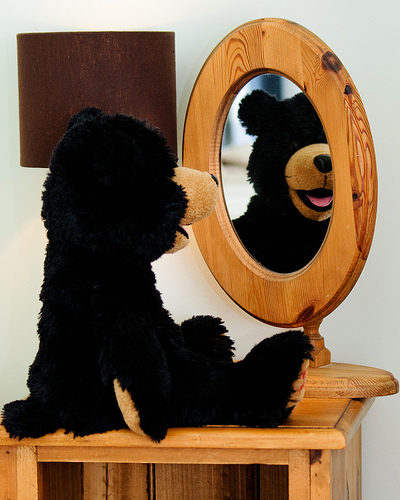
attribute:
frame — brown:
[175, 22, 390, 324]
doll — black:
[0, 97, 326, 439]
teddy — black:
[96, 270, 131, 310]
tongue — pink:
[307, 192, 333, 206]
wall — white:
[336, 1, 399, 55]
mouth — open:
[290, 185, 337, 213]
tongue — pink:
[302, 189, 334, 209]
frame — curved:
[182, 19, 387, 381]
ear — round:
[237, 85, 277, 138]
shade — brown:
[17, 28, 178, 168]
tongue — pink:
[294, 187, 333, 209]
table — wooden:
[11, 353, 387, 497]